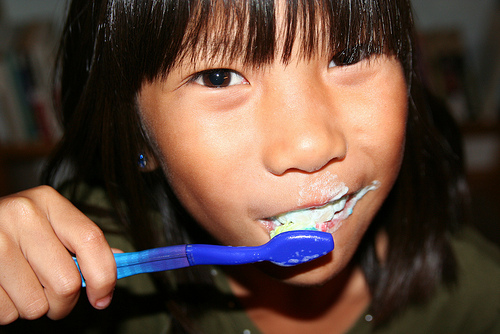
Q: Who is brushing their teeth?
A: Girl.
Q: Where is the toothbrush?
A: In her mouth.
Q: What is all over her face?
A: Toothpaste.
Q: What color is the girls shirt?
A: Green.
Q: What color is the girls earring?
A: Blue.